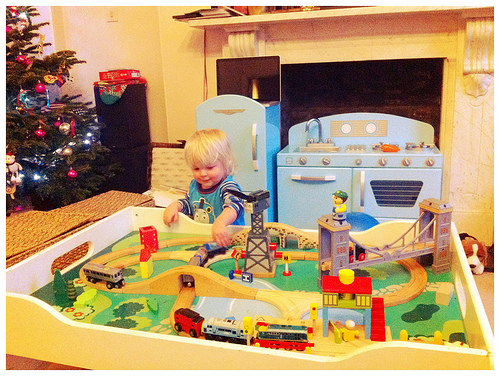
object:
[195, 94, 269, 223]
chair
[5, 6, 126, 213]
christmas tree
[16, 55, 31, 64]
decoration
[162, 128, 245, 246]
small child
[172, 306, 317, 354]
toy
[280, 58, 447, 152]
fire place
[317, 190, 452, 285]
toy bridge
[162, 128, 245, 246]
child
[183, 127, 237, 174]
hair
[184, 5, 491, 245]
fireplace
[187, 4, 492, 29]
mantle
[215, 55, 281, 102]
computer monitor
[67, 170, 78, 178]
ball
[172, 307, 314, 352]
train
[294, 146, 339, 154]
sink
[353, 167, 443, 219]
stove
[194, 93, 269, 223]
toy refrigerator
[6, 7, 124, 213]
tree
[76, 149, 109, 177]
leaves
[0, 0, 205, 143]
wall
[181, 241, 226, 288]
train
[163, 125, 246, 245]
baby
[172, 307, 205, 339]
caboose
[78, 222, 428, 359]
track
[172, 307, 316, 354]
cars